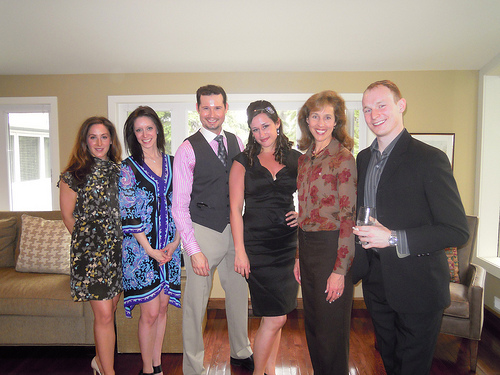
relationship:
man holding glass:
[349, 77, 470, 373] [346, 201, 380, 250]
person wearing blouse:
[295, 88, 355, 373] [298, 141, 357, 275]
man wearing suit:
[349, 77, 470, 373] [355, 128, 470, 374]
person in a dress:
[56, 114, 124, 373] [60, 169, 118, 303]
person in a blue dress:
[118, 105, 182, 373] [119, 151, 184, 318]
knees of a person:
[145, 305, 157, 322] [118, 105, 182, 373]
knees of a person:
[157, 297, 168, 314] [118, 105, 182, 373]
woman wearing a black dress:
[224, 98, 303, 373] [232, 147, 304, 317]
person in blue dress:
[118, 105, 182, 373] [119, 151, 184, 318]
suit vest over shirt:
[186, 130, 238, 231] [154, 124, 250, 261]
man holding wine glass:
[349, 77, 470, 373] [351, 206, 384, 247]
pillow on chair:
[439, 240, 462, 279] [397, 215, 485, 372]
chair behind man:
[382, 201, 484, 371] [347, 63, 497, 373]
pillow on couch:
[15, 215, 74, 271] [0, 205, 127, 344]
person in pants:
[295, 88, 355, 373] [297, 229, 358, 374]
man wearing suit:
[349, 77, 470, 373] [344, 130, 471, 312]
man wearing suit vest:
[176, 85, 226, 373] [186, 130, 238, 231]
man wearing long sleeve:
[176, 85, 226, 373] [168, 125, 248, 256]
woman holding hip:
[224, 98, 303, 373] [279, 204, 299, 239]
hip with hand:
[279, 204, 299, 239] [284, 207, 300, 230]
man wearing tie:
[176, 85, 251, 375] [214, 135, 228, 164]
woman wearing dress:
[224, 98, 303, 373] [233, 145, 303, 317]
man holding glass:
[349, 77, 470, 373] [351, 199, 393, 256]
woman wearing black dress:
[224, 98, 303, 373] [232, 147, 304, 317]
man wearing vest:
[176, 85, 251, 375] [182, 124, 232, 232]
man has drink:
[349, 77, 470, 373] [353, 207, 373, 244]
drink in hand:
[353, 207, 373, 244] [352, 214, 391, 248]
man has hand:
[349, 77, 470, 373] [352, 214, 391, 248]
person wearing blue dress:
[118, 105, 182, 373] [119, 151, 184, 312]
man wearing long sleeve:
[176, 85, 251, 375] [168, 125, 248, 256]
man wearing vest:
[176, 85, 251, 375] [183, 128, 242, 233]